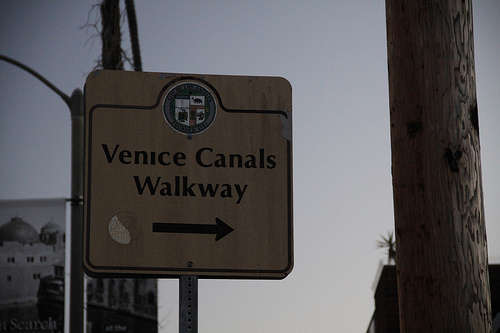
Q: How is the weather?
A: It is clear.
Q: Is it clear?
A: Yes, it is clear.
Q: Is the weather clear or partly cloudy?
A: It is clear.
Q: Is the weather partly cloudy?
A: No, it is clear.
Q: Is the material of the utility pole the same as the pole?
A: No, the utility pole is made of wood and the pole is made of metal.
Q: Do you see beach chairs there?
A: No, there are no beach chairs.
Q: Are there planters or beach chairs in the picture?
A: No, there are no beach chairs or planters.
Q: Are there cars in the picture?
A: No, there are no cars.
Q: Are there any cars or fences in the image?
A: No, there are no cars or fences.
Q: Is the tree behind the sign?
A: Yes, the tree is behind the sign.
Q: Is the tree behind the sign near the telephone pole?
A: Yes, the tree is behind the sign.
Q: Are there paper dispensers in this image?
A: No, there are no paper dispensers.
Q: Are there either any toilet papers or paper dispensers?
A: No, there are no paper dispensers or toilet papers.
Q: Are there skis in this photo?
A: No, there are no skis.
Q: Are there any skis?
A: No, there are no skis.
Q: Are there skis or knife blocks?
A: No, there are no skis or knife blocks.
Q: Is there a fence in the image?
A: No, there are no fences.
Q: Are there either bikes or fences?
A: No, there are no fences or bikes.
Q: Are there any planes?
A: No, there are no planes.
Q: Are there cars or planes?
A: No, there are no planes or cars.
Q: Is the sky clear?
A: Yes, the sky is clear.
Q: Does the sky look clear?
A: Yes, the sky is clear.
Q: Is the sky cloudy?
A: No, the sky is clear.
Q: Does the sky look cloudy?
A: No, the sky is clear.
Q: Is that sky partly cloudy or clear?
A: The sky is clear.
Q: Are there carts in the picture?
A: No, there are no carts.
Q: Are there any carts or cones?
A: No, there are no carts or cones.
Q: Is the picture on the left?
A: Yes, the picture is on the left of the image.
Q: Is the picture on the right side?
A: No, the picture is on the left of the image.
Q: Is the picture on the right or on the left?
A: The picture is on the left of the image.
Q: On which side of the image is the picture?
A: The picture is on the left of the image.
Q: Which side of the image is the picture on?
A: The picture is on the left of the image.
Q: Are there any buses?
A: No, there are no buses.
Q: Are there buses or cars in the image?
A: No, there are no buses or cars.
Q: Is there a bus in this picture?
A: No, there are no buses.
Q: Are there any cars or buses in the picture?
A: No, there are no buses or cars.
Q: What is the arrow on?
A: The arrow is on the sign.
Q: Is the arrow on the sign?
A: Yes, the arrow is on the sign.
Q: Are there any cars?
A: No, there are no cars.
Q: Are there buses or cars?
A: No, there are no cars or buses.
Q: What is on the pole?
A: The sign is on the pole.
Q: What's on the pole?
A: The sign is on the pole.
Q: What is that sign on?
A: The sign is on the pole.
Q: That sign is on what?
A: The sign is on the pole.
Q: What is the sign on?
A: The sign is on the pole.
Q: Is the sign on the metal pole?
A: Yes, the sign is on the pole.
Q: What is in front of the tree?
A: The sign is in front of the tree.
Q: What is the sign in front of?
A: The sign is in front of the tree.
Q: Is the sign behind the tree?
A: No, the sign is in front of the tree.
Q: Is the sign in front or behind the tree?
A: The sign is in front of the tree.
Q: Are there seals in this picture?
A: Yes, there is a seal.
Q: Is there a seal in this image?
A: Yes, there is a seal.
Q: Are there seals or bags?
A: Yes, there is a seal.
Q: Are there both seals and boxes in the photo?
A: No, there is a seal but no boxes.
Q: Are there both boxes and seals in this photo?
A: No, there is a seal but no boxes.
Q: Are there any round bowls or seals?
A: Yes, there is a round seal.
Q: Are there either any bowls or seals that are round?
A: Yes, the seal is round.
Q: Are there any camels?
A: No, there are no camels.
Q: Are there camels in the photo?
A: No, there are no camels.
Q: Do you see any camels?
A: No, there are no camels.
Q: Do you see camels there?
A: No, there are no camels.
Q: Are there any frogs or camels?
A: No, there are no camels or frogs.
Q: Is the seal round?
A: Yes, the seal is round.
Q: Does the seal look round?
A: Yes, the seal is round.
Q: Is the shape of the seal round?
A: Yes, the seal is round.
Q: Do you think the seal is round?
A: Yes, the seal is round.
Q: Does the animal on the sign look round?
A: Yes, the seal is round.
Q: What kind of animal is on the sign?
A: The animal is a seal.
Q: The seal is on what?
A: The seal is on the sign.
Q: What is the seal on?
A: The seal is on the sign.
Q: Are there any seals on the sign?
A: Yes, there is a seal on the sign.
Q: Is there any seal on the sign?
A: Yes, there is a seal on the sign.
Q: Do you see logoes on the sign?
A: No, there is a seal on the sign.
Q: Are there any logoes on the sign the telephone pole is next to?
A: No, there is a seal on the sign.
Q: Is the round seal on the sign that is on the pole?
A: Yes, the seal is on the sign.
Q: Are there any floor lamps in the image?
A: No, there are no floor lamps.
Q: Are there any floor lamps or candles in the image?
A: No, there are no floor lamps or candles.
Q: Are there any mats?
A: No, there are no mats.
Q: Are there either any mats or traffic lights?
A: No, there are no mats or traffic lights.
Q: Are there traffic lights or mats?
A: No, there are no mats or traffic lights.